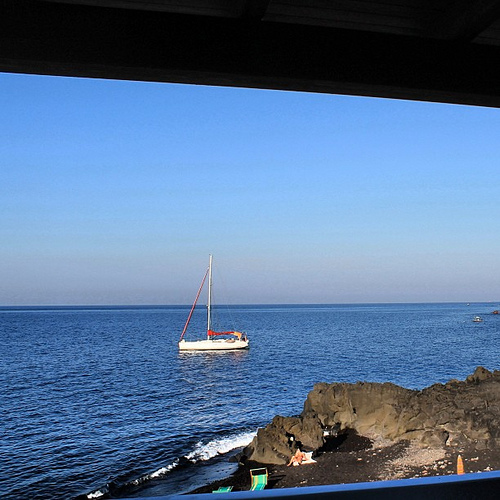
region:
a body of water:
[35, 314, 481, 417]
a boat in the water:
[150, 245, 282, 369]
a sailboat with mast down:
[132, 240, 283, 382]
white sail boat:
[158, 307, 260, 362]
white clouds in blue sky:
[25, 216, 64, 251]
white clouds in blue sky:
[383, 203, 418, 244]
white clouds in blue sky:
[114, 153, 129, 179]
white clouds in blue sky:
[0, 236, 36, 271]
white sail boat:
[161, 333, 256, 368]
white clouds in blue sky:
[59, 121, 72, 143]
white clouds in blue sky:
[404, 234, 486, 272]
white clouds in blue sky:
[363, 211, 378, 242]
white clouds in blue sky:
[421, 161, 478, 220]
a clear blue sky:
[12, 65, 435, 360]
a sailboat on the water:
[128, 247, 360, 438]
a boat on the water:
[111, 212, 378, 419]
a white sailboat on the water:
[155, 238, 268, 373]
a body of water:
[214, 281, 492, 372]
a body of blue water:
[254, 298, 439, 401]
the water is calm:
[40, 331, 185, 444]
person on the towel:
[290, 447, 306, 466]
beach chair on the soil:
[247, 465, 282, 491]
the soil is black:
[274, 467, 409, 492]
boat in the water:
[52, 314, 182, 432]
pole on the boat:
[199, 255, 224, 342]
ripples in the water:
[105, 365, 265, 428]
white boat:
[162, 291, 279, 383]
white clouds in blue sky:
[26, 158, 63, 196]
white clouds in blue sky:
[304, 243, 337, 274]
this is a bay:
[71, 271, 426, 483]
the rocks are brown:
[294, 373, 399, 435]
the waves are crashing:
[150, 415, 271, 463]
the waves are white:
[188, 375, 295, 488]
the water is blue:
[32, 345, 186, 458]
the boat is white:
[94, 208, 262, 373]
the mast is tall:
[158, 250, 243, 346]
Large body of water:
[13, 353, 110, 428]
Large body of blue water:
[18, 363, 136, 441]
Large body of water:
[8, 314, 97, 373]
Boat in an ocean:
[155, 247, 259, 359]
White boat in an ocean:
[163, 248, 255, 357]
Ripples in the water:
[24, 366, 134, 450]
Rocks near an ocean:
[221, 363, 420, 446]